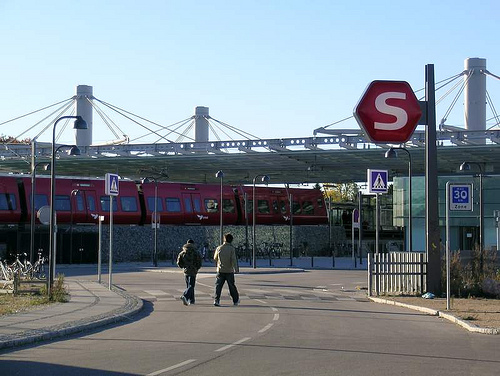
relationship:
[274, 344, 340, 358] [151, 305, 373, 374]
part of road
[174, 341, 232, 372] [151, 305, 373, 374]
lines on road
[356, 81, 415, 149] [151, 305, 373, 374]
sign for road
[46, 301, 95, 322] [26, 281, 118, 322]
path for walking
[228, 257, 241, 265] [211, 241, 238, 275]
part of jacket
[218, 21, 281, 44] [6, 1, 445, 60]
part of sky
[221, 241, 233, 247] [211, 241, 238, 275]
hood on jacket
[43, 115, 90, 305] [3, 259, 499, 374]
lamp on road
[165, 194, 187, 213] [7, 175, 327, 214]
window on train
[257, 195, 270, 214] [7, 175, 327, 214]
window on train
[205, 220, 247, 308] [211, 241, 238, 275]
man in jacket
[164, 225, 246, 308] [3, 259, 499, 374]
people on road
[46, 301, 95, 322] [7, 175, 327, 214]
path to train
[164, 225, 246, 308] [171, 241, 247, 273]
people wearing coats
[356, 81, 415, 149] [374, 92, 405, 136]
sign with s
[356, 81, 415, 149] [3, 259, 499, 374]
sign on road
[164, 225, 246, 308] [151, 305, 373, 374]
people in road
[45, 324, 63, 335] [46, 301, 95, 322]
boards on path